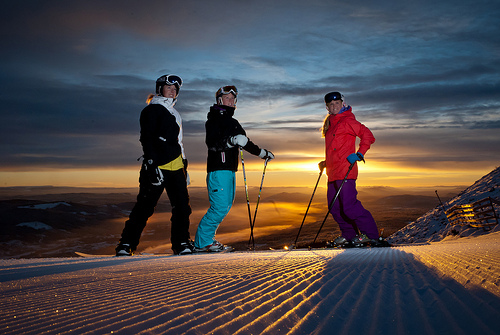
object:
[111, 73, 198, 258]
person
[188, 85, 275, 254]
person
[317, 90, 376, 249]
person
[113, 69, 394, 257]
people